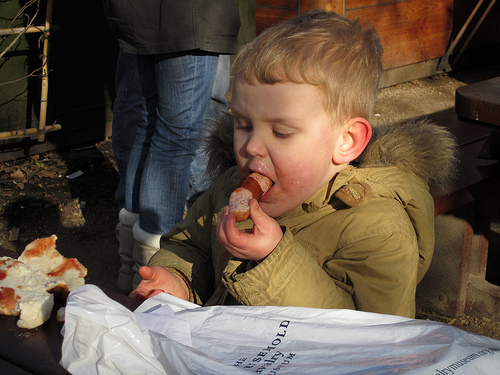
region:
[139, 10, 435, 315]
a young boy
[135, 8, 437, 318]
a young boy eating a wurst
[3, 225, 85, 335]
a bread bun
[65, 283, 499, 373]
a white plastic bag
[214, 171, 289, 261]
a hand holding a wurst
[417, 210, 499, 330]
a wooden chair top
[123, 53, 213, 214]
blue jeans glad legs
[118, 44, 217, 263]
blue jeans glad legs in boots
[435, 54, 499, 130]
wooden table top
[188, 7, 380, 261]
boy looking at his hand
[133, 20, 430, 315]
A little boy eating.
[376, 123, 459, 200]
Fur on the boy's jacket.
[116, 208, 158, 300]
A pair of brown boots.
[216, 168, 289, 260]
The boy is eating a hot dog.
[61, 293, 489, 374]
A white plastic bag.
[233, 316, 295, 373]
Some writing on the front of the bag.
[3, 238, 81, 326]
A piece of the bread.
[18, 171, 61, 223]
Part of the dirt on the ground.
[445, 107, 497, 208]
Part of the bench.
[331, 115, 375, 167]
The boy's left ear.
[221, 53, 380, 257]
this is a baby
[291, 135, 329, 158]
the baby is light skinned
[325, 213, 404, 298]
this is a jacket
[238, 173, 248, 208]
this is a snack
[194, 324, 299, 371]
this is a sack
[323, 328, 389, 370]
the sack is white in color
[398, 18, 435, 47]
this is a cupboard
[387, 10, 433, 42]
the board is brown in color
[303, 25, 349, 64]
this is the hair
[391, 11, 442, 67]
the board is wooden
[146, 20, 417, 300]
small child eating a hot dog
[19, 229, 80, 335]
hot dog bun with ketchup on it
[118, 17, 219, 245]
person wearing blue jeans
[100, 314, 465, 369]
white plastic bag with black lettering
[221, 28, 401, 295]
small boy with blonde hair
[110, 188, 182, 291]
person wearing winter boots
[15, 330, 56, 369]
brown wooden table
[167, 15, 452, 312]
boy wearing an olive green winter jacket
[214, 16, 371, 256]
boy eating hot dog without the bun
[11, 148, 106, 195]
leaves scattered on ground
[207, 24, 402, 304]
this is a small boy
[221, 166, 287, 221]
the boy is eating sausage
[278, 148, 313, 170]
the boy is light skinned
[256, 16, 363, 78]
the hair is short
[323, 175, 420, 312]
the jacket is warm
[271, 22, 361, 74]
the hair is pale brown in color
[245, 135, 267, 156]
the nose is small in size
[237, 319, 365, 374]
this is a paper bag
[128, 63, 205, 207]
she is wearing jeans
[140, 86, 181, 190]
the jeans is blue in color